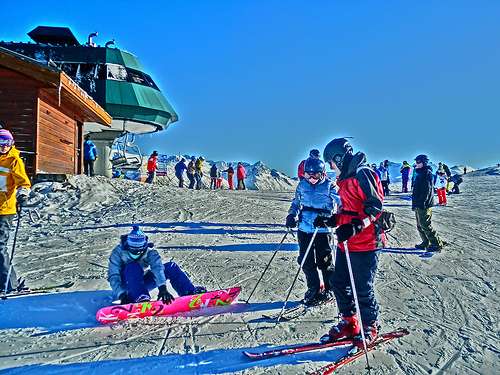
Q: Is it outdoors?
A: Yes, it is outdoors.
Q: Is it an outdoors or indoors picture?
A: It is outdoors.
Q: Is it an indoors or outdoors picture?
A: It is outdoors.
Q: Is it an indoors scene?
A: No, it is outdoors.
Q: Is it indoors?
A: No, it is outdoors.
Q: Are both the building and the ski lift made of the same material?
A: No, the building is made of wood and the ski lift is made of metal.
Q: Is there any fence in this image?
A: No, there are no fences.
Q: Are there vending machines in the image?
A: No, there are no vending machines.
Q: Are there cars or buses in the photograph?
A: No, there are no cars or buses.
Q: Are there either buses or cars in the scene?
A: No, there are no cars or buses.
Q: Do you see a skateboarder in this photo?
A: Yes, there is a skateboarder.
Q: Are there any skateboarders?
A: Yes, there is a skateboarder.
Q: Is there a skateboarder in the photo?
A: Yes, there is a skateboarder.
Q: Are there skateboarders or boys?
A: Yes, there is a skateboarder.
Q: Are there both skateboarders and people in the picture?
A: Yes, there are both a skateboarder and people.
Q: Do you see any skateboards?
A: No, there are no skateboards.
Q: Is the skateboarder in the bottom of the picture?
A: Yes, the skateboarder is in the bottom of the image.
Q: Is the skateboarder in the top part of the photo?
A: No, the skateboarder is in the bottom of the image.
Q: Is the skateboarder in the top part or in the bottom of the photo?
A: The skateboarder is in the bottom of the image.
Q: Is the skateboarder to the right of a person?
A: No, the skateboarder is to the left of a person.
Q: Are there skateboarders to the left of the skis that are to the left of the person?
A: Yes, there is a skateboarder to the left of the skis.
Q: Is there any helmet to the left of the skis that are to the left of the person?
A: No, there is a skateboarder to the left of the skis.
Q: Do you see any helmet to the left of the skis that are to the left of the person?
A: No, there is a skateboarder to the left of the skis.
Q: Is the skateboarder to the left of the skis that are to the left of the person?
A: Yes, the skateboarder is to the left of the skis.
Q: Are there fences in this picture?
A: No, there are no fences.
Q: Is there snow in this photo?
A: Yes, there is snow.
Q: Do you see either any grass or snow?
A: Yes, there is snow.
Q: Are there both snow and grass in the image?
A: No, there is snow but no grass.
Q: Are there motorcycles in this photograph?
A: No, there are no motorcycles.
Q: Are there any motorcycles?
A: No, there are no motorcycles.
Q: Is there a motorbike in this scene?
A: No, there are no motorcycles.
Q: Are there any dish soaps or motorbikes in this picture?
A: No, there are no motorbikes or dish soaps.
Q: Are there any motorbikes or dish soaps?
A: No, there are no motorbikes or dish soaps.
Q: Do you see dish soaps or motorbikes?
A: No, there are no motorbikes or dish soaps.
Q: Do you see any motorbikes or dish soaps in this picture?
A: No, there are no motorbikes or dish soaps.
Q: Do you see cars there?
A: No, there are no cars.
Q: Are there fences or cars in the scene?
A: No, there are no cars or fences.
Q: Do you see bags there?
A: No, there are no bags.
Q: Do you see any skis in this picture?
A: Yes, there are skis.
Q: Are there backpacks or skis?
A: Yes, there are skis.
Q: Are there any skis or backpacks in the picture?
A: Yes, there are skis.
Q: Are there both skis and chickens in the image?
A: No, there are skis but no chickens.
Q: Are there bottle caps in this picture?
A: No, there are no bottle caps.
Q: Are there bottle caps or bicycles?
A: No, there are no bottle caps or bicycles.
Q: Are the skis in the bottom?
A: Yes, the skis are in the bottom of the image.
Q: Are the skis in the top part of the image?
A: No, the skis are in the bottom of the image.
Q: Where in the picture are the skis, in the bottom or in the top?
A: The skis are in the bottom of the image.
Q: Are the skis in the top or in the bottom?
A: The skis are in the bottom of the image.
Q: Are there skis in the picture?
A: Yes, there are skis.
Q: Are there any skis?
A: Yes, there are skis.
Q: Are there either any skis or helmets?
A: Yes, there are skis.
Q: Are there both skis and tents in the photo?
A: No, there are skis but no tents.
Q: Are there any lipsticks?
A: No, there are no lipsticks.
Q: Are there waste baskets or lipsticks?
A: No, there are no lipsticks or waste baskets.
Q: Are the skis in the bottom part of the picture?
A: Yes, the skis are in the bottom of the image.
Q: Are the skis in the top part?
A: No, the skis are in the bottom of the image.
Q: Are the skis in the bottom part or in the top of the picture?
A: The skis are in the bottom of the image.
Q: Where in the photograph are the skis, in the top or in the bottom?
A: The skis are in the bottom of the image.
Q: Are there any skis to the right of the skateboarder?
A: Yes, there are skis to the right of the skateboarder.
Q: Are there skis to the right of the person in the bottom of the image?
A: Yes, there are skis to the right of the skateboarder.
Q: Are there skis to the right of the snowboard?
A: Yes, there are skis to the right of the snowboard.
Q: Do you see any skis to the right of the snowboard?
A: Yes, there are skis to the right of the snowboard.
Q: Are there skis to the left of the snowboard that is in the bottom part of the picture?
A: No, the skis are to the right of the snow board.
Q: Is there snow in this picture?
A: Yes, there is snow.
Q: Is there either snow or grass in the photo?
A: Yes, there is snow.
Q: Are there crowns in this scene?
A: No, there are no crowns.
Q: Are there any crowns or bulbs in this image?
A: No, there are no crowns or bulbs.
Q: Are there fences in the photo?
A: No, there are no fences.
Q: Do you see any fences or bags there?
A: No, there are no fences or bags.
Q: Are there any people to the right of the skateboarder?
A: Yes, there is a person to the right of the skateboarder.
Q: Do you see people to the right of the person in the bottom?
A: Yes, there is a person to the right of the skateboarder.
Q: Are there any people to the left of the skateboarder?
A: No, the person is to the right of the skateboarder.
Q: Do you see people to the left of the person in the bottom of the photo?
A: No, the person is to the right of the skateboarder.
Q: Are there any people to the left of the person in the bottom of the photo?
A: No, the person is to the right of the skateboarder.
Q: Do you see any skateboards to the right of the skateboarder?
A: No, there is a person to the right of the skateboarder.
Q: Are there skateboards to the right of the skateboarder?
A: No, there is a person to the right of the skateboarder.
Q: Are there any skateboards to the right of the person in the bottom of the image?
A: No, there is a person to the right of the skateboarder.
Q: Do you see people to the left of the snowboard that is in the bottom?
A: No, the person is to the right of the snowboard.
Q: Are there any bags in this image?
A: No, there are no bags.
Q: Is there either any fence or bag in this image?
A: No, there are no bags or fences.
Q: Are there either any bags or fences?
A: No, there are no bags or fences.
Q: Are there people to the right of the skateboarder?
A: Yes, there is a person to the right of the skateboarder.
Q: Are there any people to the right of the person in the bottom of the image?
A: Yes, there is a person to the right of the skateboarder.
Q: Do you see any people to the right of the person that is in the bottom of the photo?
A: Yes, there is a person to the right of the skateboarder.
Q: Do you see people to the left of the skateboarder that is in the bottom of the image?
A: No, the person is to the right of the skateboarder.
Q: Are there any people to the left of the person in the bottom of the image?
A: No, the person is to the right of the skateboarder.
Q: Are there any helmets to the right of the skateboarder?
A: No, there is a person to the right of the skateboarder.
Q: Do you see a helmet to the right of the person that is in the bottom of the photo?
A: No, there is a person to the right of the skateboarder.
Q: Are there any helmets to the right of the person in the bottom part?
A: No, there is a person to the right of the skateboarder.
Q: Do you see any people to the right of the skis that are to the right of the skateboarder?
A: Yes, there is a person to the right of the skis.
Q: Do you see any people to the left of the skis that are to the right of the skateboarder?
A: No, the person is to the right of the skis.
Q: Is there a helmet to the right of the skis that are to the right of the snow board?
A: No, there is a person to the right of the skis.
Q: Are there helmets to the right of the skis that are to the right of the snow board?
A: No, there is a person to the right of the skis.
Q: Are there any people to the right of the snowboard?
A: Yes, there is a person to the right of the snowboard.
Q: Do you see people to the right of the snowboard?
A: Yes, there is a person to the right of the snowboard.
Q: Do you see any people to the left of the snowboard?
A: No, the person is to the right of the snowboard.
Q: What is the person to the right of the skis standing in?
A: The person is standing in the snow.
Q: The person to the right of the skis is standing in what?
A: The person is standing in the snow.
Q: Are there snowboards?
A: Yes, there is a snowboard.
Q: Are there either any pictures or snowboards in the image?
A: Yes, there is a snowboard.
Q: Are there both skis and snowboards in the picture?
A: Yes, there are both a snowboard and skis.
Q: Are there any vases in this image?
A: No, there are no vases.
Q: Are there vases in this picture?
A: No, there are no vases.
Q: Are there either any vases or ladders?
A: No, there are no vases or ladders.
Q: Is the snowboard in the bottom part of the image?
A: Yes, the snowboard is in the bottom of the image.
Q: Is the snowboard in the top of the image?
A: No, the snowboard is in the bottom of the image.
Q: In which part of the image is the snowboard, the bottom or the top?
A: The snowboard is in the bottom of the image.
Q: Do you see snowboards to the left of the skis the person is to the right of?
A: Yes, there is a snowboard to the left of the skis.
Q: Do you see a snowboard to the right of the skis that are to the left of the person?
A: No, the snowboard is to the left of the skis.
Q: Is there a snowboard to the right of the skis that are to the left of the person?
A: No, the snowboard is to the left of the skis.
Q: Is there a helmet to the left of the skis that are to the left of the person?
A: No, there is a snowboard to the left of the skis.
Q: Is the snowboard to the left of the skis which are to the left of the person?
A: Yes, the snowboard is to the left of the skis.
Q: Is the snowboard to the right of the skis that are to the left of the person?
A: No, the snowboard is to the left of the skis.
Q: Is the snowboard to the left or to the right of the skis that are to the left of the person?
A: The snowboard is to the left of the skis.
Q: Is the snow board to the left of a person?
A: Yes, the snow board is to the left of a person.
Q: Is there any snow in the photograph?
A: Yes, there is snow.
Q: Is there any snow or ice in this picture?
A: Yes, there is snow.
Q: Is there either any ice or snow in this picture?
A: Yes, there is snow.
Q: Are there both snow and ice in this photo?
A: No, there is snow but no ice.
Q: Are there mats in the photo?
A: No, there are no mats.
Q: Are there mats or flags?
A: No, there are no mats or flags.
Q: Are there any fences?
A: No, there are no fences.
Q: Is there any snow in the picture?
A: Yes, there is snow.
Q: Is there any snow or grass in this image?
A: Yes, there is snow.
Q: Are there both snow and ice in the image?
A: No, there is snow but no ice.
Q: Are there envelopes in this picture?
A: No, there are no envelopes.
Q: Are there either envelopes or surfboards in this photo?
A: No, there are no envelopes or surfboards.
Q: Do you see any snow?
A: Yes, there is snow.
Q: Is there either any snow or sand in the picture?
A: Yes, there is snow.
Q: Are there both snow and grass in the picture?
A: No, there is snow but no grass.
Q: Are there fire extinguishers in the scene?
A: No, there are no fire extinguishers.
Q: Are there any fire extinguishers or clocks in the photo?
A: No, there are no fire extinguishers or clocks.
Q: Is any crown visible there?
A: No, there are no crowns.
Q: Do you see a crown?
A: No, there are no crowns.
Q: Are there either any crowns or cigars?
A: No, there are no crowns or cigars.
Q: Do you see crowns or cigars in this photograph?
A: No, there are no crowns or cigars.